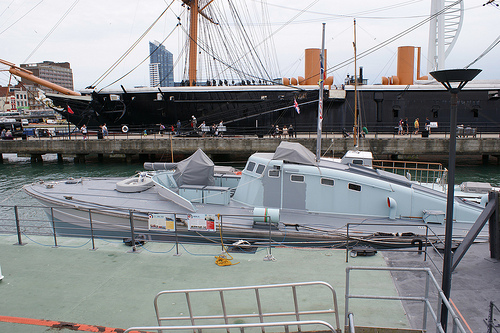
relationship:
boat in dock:
[17, 141, 497, 251] [1, 205, 498, 331]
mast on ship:
[126, 1, 308, 88] [1, 2, 499, 133]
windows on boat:
[348, 181, 361, 190] [20, 141, 497, 251]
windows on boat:
[321, 175, 338, 187] [20, 141, 497, 251]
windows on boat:
[290, 173, 309, 182] [20, 141, 497, 251]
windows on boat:
[267, 168, 281, 180] [20, 141, 497, 251]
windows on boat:
[244, 158, 266, 176] [20, 141, 497, 251]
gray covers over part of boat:
[174, 151, 222, 188] [47, 129, 484, 233]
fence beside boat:
[0, 201, 295, 256] [17, 141, 497, 251]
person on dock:
[80, 124, 88, 139] [0, 136, 498, 162]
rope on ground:
[215, 216, 240, 267] [2, 234, 497, 330]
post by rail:
[438, 90, 460, 331] [342, 264, 467, 331]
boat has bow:
[17, 141, 497, 251] [26, 165, 108, 217]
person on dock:
[77, 123, 97, 137] [13, 136, 490, 153]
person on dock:
[99, 123, 109, 133] [13, 136, 490, 153]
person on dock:
[285, 124, 297, 133] [13, 136, 490, 153]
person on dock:
[395, 121, 406, 133] [13, 136, 490, 153]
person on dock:
[427, 119, 439, 131] [13, 136, 490, 153]